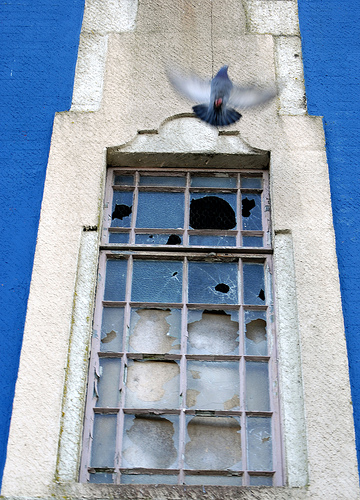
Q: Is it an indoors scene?
A: Yes, it is indoors.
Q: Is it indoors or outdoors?
A: It is indoors.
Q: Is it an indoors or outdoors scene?
A: It is indoors.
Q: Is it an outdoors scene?
A: No, it is indoors.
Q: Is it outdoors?
A: No, it is indoors.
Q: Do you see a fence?
A: No, there are no fences.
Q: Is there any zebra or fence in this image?
A: No, there are no fences or zebras.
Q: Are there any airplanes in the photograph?
A: No, there are no airplanes.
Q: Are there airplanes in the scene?
A: No, there are no airplanes.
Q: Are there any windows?
A: Yes, there are windows.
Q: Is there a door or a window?
A: Yes, there are windows.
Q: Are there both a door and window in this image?
A: No, there are windows but no doors.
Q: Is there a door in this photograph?
A: No, there are no doors.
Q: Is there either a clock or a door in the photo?
A: No, there are no doors or clocks.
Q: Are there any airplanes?
A: No, there are no airplanes.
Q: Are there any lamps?
A: No, there are no lamps.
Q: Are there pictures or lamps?
A: No, there are no lamps or pictures.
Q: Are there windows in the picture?
A: Yes, there is a window.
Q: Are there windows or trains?
A: Yes, there is a window.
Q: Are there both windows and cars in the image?
A: No, there is a window but no cars.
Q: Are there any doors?
A: No, there are no doors.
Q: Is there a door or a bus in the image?
A: No, there are no doors or buses.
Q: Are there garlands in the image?
A: No, there are no garlands.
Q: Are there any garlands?
A: No, there are no garlands.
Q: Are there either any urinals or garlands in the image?
A: No, there are no garlands or urinals.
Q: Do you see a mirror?
A: No, there are no mirrors.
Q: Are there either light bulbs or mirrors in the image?
A: No, there are no mirrors or light bulbs.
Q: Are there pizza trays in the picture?
A: No, there are no pizza trays.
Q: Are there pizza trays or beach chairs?
A: No, there are no pizza trays or beach chairs.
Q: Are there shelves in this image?
A: No, there are no shelves.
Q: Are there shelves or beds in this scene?
A: No, there are no shelves or beds.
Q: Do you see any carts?
A: No, there are no carts.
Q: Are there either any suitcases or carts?
A: No, there are no carts or suitcases.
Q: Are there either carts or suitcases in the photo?
A: No, there are no carts or suitcases.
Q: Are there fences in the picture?
A: No, there are no fences.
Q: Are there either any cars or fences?
A: No, there are no fences or cars.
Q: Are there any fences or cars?
A: No, there are no fences or cars.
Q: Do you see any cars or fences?
A: No, there are no fences or cars.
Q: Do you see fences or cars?
A: No, there are no fences or cars.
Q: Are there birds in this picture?
A: Yes, there is a bird.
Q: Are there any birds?
A: Yes, there is a bird.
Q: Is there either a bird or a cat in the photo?
A: Yes, there is a bird.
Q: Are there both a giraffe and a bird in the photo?
A: No, there is a bird but no giraffes.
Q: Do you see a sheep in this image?
A: No, there is no sheep.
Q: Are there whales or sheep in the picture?
A: No, there are no sheep or whales.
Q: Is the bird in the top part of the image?
A: Yes, the bird is in the top of the image.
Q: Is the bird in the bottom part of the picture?
A: No, the bird is in the top of the image.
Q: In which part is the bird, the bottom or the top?
A: The bird is in the top of the image.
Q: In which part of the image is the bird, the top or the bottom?
A: The bird is in the top of the image.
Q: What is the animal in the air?
A: The animal is a bird.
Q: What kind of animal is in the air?
A: The animal is a bird.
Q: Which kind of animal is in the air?
A: The animal is a bird.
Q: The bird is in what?
A: The bird is in the air.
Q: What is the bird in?
A: The bird is in the air.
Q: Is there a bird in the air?
A: Yes, there is a bird in the air.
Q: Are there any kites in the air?
A: No, there is a bird in the air.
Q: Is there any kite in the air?
A: No, there is a bird in the air.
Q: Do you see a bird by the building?
A: Yes, there is a bird by the building.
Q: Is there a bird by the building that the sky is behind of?
A: Yes, there is a bird by the building.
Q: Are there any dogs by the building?
A: No, there is a bird by the building.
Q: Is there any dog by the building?
A: No, there is a bird by the building.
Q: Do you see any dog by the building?
A: No, there is a bird by the building.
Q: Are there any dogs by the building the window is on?
A: No, there is a bird by the building.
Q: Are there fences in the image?
A: No, there are no fences.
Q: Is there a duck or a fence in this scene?
A: No, there are no fences or ducks.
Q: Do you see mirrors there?
A: No, there are no mirrors.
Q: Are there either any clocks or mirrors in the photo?
A: No, there are no mirrors or clocks.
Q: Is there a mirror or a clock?
A: No, there are no mirrors or clocks.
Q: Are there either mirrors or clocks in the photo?
A: No, there are no mirrors or clocks.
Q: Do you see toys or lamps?
A: No, there are no lamps or toys.